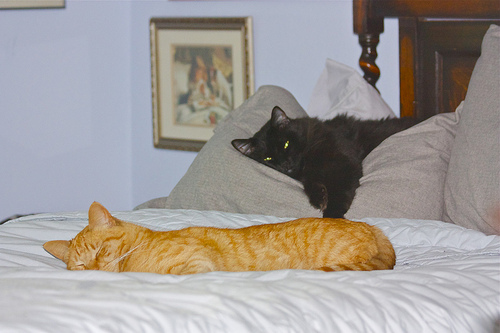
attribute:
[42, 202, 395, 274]
cat — orange, sleeping, laying, yellow, asleep, existing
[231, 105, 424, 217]
cat — black, observing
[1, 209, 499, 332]
comforter — white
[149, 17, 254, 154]
picture — hanging, framed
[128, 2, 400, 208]
wall — blue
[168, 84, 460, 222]
pillow — existing, grey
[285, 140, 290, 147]
eye — open, green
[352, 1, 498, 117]
headboard — wood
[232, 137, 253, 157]
ear — black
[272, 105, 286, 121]
ear — black